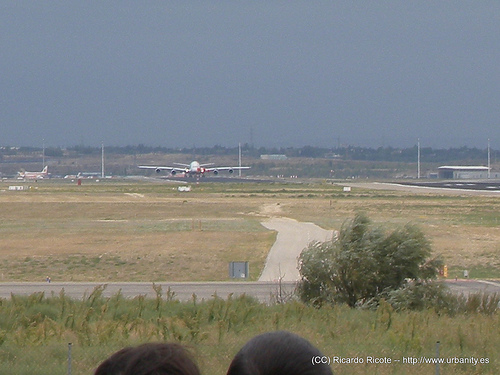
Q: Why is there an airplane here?
A: It is an airfield.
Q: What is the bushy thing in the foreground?
A: Tree.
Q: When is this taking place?
A: Late afternoon.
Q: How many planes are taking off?
A: 1.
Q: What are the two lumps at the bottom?
A: Peoples' heads.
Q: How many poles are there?
A: 5.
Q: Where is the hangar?
A: On the right.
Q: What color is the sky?
A: Gray.